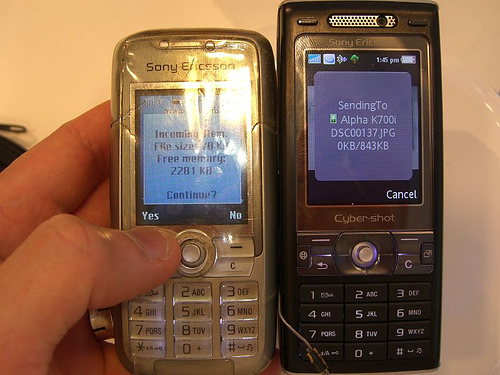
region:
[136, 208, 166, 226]
yes on silver phone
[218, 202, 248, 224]
no on silver phone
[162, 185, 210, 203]
word continue on silver phone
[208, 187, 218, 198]
question mark on screen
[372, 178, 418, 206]
cancel icon on black phone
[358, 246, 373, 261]
menu button on black phone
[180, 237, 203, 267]
menu button on silver phone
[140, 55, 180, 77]
word sony on phone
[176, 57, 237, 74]
word ecrisson on phone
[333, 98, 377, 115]
word sending on screen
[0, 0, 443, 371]
two small phones being held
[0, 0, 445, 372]
two cellphones in a person's hand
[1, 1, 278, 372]
silver phone in a person's hand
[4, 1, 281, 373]
cell in a person's hand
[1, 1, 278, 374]
silver sony ericson phone in a persons hand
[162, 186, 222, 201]
text print reading Continue?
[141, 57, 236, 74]
print reading Sony Ericson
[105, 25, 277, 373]
glare on a silver cellphone with small buttons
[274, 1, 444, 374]
black sony ericson cybershot cellphone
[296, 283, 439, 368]
black and white keypad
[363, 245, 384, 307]
There is a power button that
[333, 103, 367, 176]
There is a very bright screen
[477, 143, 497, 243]
There is a white wall that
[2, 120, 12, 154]
There is a black pouch that is visible here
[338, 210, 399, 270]
This phone says "Cyber-shot" on it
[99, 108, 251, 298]
Jackson Mingus took this photo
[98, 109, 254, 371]
Zander Zane owns this photo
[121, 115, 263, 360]
This photo was taken last week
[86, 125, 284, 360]
This photo is rather vivid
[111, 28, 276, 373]
Silver Sony Ericsson cell phone.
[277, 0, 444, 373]
Black Sony Ericsson cell phone.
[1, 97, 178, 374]
Hand holding the phones.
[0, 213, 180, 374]
Thumb on the hand holding the phones.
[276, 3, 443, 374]
Cell phone on the right.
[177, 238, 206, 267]
Round button on silver phone.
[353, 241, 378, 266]
Round button on black phone.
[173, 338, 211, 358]
0 button on silver phone.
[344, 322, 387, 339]
8 button on black phone.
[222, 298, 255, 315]
key on cell phone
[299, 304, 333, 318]
key on cell phone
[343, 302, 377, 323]
key on cell phone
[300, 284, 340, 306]
key on cell phone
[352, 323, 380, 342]
key on cell phone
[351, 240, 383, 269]
key on cell phone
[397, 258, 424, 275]
key on cell phone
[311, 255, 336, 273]
key on cell phone